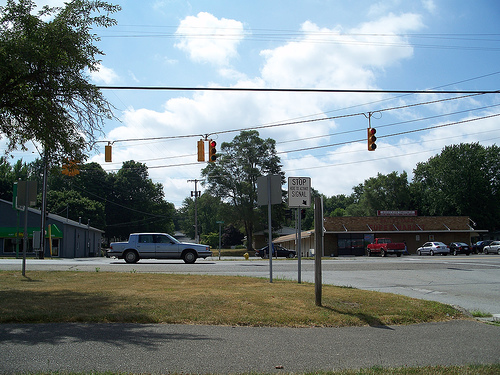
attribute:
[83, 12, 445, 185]
clouds — white 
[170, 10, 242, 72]
cloud — white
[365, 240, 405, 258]
truck — red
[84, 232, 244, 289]
car — light, blue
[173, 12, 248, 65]
cloud — white 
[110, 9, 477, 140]
sky — cloudy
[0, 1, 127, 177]
tree — green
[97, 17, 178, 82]
sky — blue 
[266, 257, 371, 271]
road — brown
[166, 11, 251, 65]
cloud — white 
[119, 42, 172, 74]
sky — blue 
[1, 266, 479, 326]
grass — green, barren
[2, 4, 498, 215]
sky — blue , cloudy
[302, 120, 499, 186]
clouds — white 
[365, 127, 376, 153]
street light — yellow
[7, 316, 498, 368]
walkway — asphalt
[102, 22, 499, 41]
power line — long, electrical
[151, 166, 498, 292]
cars — parked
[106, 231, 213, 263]
gray car — old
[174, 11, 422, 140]
clouds — big, puffy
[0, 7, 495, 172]
lines — power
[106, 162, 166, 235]
tree — tall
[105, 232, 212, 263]
car — small, white